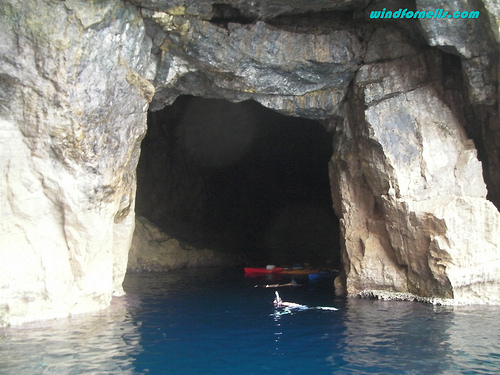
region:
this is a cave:
[110, 105, 350, 331]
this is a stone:
[337, 108, 499, 288]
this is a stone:
[181, 8, 366, 109]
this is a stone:
[1, 69, 126, 329]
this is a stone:
[22, 7, 152, 126]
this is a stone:
[411, 2, 495, 98]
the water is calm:
[204, 283, 321, 364]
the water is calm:
[188, 299, 279, 370]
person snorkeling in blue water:
[268, 289, 338, 324]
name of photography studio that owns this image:
[369, 4, 488, 28]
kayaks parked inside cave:
[240, 257, 340, 292]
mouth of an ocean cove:
[105, 68, 402, 316]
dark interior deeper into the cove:
[189, 130, 320, 242]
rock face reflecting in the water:
[0, 297, 143, 374]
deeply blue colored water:
[184, 298, 270, 361]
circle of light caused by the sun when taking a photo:
[180, 91, 259, 171]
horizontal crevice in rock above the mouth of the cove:
[205, 8, 370, 35]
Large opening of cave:
[107, 73, 369, 323]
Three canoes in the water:
[236, 248, 346, 295]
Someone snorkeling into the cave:
[269, 287, 346, 324]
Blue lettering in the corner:
[365, 2, 495, 29]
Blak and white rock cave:
[0, 3, 496, 336]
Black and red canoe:
[242, 261, 289, 283]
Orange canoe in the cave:
[275, 257, 314, 283]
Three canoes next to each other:
[229, 256, 357, 308]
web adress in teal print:
[363, 5, 485, 28]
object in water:
[265, 281, 344, 326]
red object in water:
[231, 253, 309, 285]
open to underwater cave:
[92, 60, 395, 324]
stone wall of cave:
[340, 90, 497, 314]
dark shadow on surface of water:
[134, 270, 376, 370]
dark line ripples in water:
[12, 325, 118, 369]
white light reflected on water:
[450, 310, 497, 358]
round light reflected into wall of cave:
[172, 100, 271, 180]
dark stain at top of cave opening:
[201, 3, 381, 45]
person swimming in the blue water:
[262, 284, 339, 324]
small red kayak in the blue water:
[239, 259, 284, 279]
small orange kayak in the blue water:
[274, 263, 325, 280]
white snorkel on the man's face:
[272, 285, 282, 305]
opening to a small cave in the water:
[107, 93, 377, 310]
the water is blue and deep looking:
[1, 268, 498, 373]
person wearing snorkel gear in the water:
[269, 283, 343, 323]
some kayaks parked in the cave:
[235, 251, 343, 293]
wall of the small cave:
[138, 100, 330, 260]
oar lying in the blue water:
[256, 276, 301, 291]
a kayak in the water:
[222, 237, 354, 314]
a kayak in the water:
[293, 261, 321, 286]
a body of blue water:
[345, 284, 412, 373]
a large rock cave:
[347, 79, 445, 253]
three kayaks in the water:
[308, 244, 329, 290]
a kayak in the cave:
[300, 248, 330, 288]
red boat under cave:
[229, 256, 330, 286]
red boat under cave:
[225, 254, 336, 294]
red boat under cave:
[235, 245, 335, 295]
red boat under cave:
[225, 252, 333, 288]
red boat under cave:
[235, 255, 331, 295]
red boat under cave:
[231, 250, 331, 295]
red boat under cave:
[237, 253, 327, 288]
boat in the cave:
[201, 234, 342, 299]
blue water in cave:
[155, 287, 260, 362]